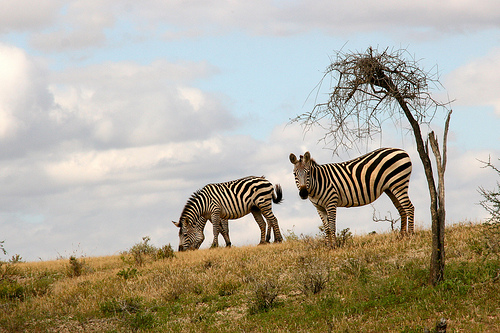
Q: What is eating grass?
A: The zebra.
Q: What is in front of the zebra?
A: A small tree.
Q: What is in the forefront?
A: Green and brown grass.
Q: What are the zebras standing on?
A: Grass.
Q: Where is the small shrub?
A: In front of the zebras.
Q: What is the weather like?
A: Partially cloudy.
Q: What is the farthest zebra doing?
A: Eating.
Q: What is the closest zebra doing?
A: Looking.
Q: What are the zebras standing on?
A: The ground.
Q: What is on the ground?
A: Grass and shrubs.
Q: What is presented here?
A: A trio of zebras.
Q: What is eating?
A: A pair of zebras.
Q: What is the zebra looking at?
A: The camera.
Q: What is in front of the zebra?
A: Small dead tree.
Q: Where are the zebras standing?
A: On the hill.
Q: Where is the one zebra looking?
A: At the camera.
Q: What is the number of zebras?
A: Two.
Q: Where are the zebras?
A: Natural habitat.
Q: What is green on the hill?
A: Grass.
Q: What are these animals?
A: Zebras.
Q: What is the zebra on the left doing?
A: Eating grass.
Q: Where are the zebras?
A: In a field.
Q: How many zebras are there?
A: Two.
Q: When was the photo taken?
A: During the daytime.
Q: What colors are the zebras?
A: White and black.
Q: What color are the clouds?
A: White.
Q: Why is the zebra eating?
A: It's hungry.